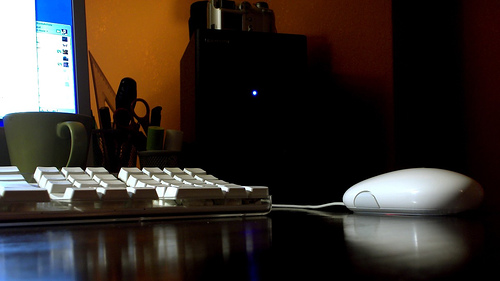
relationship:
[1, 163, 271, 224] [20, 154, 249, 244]
keyboard on desk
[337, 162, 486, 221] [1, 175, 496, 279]
mouse on table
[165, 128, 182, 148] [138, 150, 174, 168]
highlighter in cup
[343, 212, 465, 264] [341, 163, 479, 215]
reflection of mouse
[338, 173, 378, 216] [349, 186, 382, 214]
button on mouse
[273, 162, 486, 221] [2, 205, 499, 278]
mouse on table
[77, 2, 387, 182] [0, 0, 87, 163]
wall behind computer